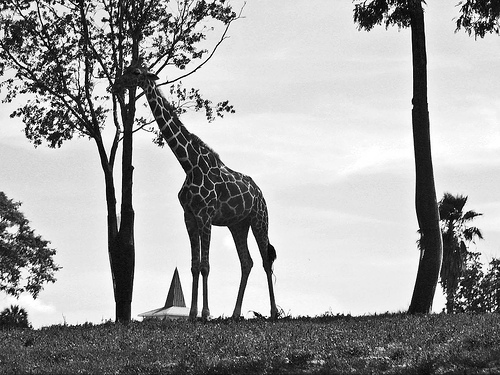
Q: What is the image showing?
A: It is showing a zoo.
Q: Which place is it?
A: It is a zoo.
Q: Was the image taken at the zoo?
A: Yes, it was taken in the zoo.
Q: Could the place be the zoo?
A: Yes, it is the zoo.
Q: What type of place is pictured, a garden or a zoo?
A: It is a zoo.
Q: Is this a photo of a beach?
A: No, the picture is showing a zoo.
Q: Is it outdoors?
A: Yes, it is outdoors.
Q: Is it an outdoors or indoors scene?
A: It is outdoors.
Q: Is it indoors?
A: No, it is outdoors.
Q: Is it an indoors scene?
A: No, it is outdoors.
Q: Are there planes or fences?
A: No, there are no fences or planes.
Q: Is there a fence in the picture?
A: No, there are no fences.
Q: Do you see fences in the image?
A: No, there are no fences.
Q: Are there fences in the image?
A: No, there are no fences.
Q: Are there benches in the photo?
A: No, there are no benches.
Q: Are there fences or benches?
A: No, there are no benches or fences.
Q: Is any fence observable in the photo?
A: No, there are no fences.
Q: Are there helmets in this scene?
A: No, there are no helmets.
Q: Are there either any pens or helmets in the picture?
A: No, there are no helmets or pens.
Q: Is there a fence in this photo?
A: No, there are no fences.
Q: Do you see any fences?
A: No, there are no fences.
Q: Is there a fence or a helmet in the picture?
A: No, there are no fences or helmets.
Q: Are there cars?
A: No, there are no cars.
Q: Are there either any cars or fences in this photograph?
A: No, there are no cars or fences.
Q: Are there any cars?
A: No, there are no cars.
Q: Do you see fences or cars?
A: No, there are no cars or fences.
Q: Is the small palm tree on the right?
A: Yes, the palm is on the right of the image.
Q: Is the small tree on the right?
A: Yes, the palm is on the right of the image.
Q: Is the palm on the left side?
A: No, the palm is on the right of the image.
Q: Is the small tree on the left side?
A: No, the palm is on the right of the image.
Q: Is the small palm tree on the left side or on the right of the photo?
A: The palm is on the right of the image.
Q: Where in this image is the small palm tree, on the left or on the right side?
A: The palm is on the right of the image.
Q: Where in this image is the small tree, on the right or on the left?
A: The palm is on the right of the image.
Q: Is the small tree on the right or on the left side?
A: The palm is on the right of the image.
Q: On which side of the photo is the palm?
A: The palm is on the right of the image.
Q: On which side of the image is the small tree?
A: The palm is on the right of the image.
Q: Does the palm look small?
A: Yes, the palm is small.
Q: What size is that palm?
A: The palm is small.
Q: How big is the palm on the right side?
A: The palm is small.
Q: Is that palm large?
A: No, the palm is small.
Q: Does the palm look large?
A: No, the palm is small.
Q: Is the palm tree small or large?
A: The palm tree is small.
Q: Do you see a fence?
A: No, there are no fences.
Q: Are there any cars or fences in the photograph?
A: No, there are no fences or cars.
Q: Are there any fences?
A: No, there are no fences.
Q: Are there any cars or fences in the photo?
A: No, there are no fences or cars.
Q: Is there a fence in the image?
A: No, there are no fences.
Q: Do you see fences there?
A: No, there are no fences.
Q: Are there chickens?
A: No, there are no chickens.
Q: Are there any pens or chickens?
A: No, there are no chickens or pens.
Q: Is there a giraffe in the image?
A: Yes, there is a giraffe.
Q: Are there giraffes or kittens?
A: Yes, there is a giraffe.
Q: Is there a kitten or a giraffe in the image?
A: Yes, there is a giraffe.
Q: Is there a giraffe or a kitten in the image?
A: Yes, there is a giraffe.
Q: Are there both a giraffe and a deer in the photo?
A: No, there is a giraffe but no deer.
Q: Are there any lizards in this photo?
A: No, there are no lizards.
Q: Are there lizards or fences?
A: No, there are no lizards or fences.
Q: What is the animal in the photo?
A: The animal is a giraffe.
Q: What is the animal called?
A: The animal is a giraffe.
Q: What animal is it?
A: The animal is a giraffe.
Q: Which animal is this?
A: That is a giraffe.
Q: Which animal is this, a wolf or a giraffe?
A: That is a giraffe.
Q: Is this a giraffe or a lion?
A: This is a giraffe.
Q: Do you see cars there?
A: No, there are no cars.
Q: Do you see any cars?
A: No, there are no cars.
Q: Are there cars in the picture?
A: No, there are no cars.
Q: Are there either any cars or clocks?
A: No, there are no cars or clocks.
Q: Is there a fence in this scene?
A: No, there are no fences.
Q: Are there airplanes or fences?
A: No, there are no fences or airplanes.